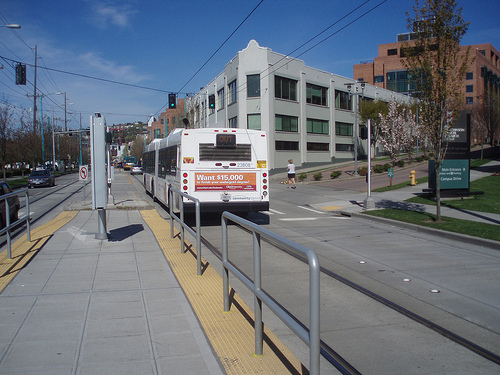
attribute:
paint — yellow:
[167, 253, 274, 348]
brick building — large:
[353, 17, 496, 142]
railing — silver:
[218, 207, 323, 374]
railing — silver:
[168, 184, 204, 271]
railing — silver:
[0, 186, 33, 263]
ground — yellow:
[5, 169, 304, 374]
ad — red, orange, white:
[197, 172, 258, 194]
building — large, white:
[184, 39, 435, 157]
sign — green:
[423, 137, 473, 194]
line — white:
[278, 215, 355, 223]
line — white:
[296, 202, 323, 214]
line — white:
[269, 206, 285, 216]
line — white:
[258, 210, 274, 217]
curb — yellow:
[122, 209, 314, 374]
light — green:
[209, 102, 216, 108]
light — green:
[170, 101, 175, 108]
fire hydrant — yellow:
[406, 170, 418, 186]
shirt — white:
[283, 157, 305, 189]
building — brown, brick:
[350, 1, 499, 187]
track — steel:
[313, 242, 475, 357]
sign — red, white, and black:
[79, 164, 88, 181]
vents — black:
[198, 143, 254, 165]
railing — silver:
[140, 171, 320, 373]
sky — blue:
[103, 47, 159, 74]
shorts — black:
[287, 171, 294, 178]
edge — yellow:
[136, 205, 308, 373]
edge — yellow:
[0, 207, 81, 294]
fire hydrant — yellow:
[407, 166, 419, 185]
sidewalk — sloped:
[365, 153, 499, 200]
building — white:
[184, 39, 445, 171]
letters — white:
[439, 165, 467, 183]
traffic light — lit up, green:
[208, 92, 217, 112]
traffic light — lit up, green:
[164, 92, 178, 109]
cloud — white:
[85, 3, 136, 33]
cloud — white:
[70, 51, 152, 89]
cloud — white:
[0, 21, 166, 138]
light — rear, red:
[181, 169, 191, 179]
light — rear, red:
[180, 180, 190, 185]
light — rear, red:
[257, 172, 270, 179]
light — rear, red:
[261, 177, 271, 186]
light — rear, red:
[262, 185, 271, 191]